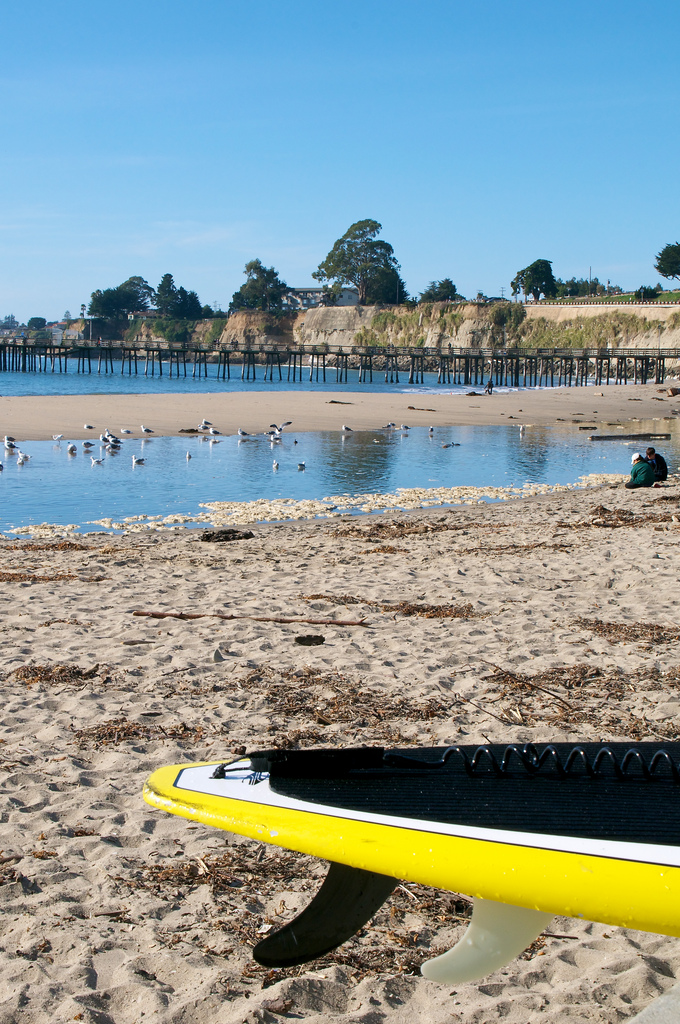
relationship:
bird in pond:
[270, 458, 280, 471] [0, 425, 677, 536]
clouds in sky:
[28, 205, 264, 269] [424, 97, 483, 201]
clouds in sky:
[0, 205, 309, 260] [492, 83, 565, 128]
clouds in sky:
[0, 205, 309, 260] [495, 137, 561, 196]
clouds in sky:
[0, 205, 309, 260] [41, 126, 89, 196]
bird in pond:
[125, 450, 153, 472] [1, 415, 675, 549]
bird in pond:
[417, 418, 446, 436] [0, 425, 677, 536]